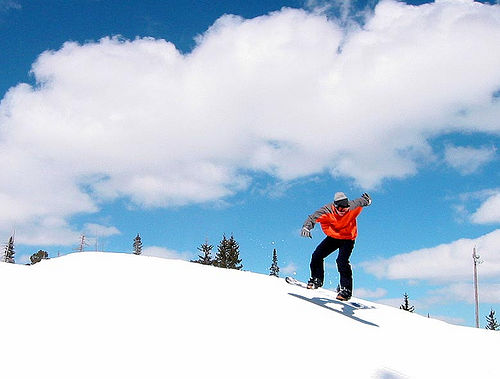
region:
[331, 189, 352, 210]
the head of a man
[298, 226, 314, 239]
the hand of a man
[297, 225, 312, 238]
a glove on the man's hand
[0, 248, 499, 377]
white snow on the ground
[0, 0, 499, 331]
a blue sky over the snow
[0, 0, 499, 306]
white clouds in the sky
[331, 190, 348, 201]
a gray hat on the man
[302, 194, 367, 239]
a gray and orange coat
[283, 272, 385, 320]
a white and gray snowboard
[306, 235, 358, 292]
a pair of black pants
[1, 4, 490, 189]
a big white clowd above the mountain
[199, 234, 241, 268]
green trees above the mountain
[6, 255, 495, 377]
a white snowy mountain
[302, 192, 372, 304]
a man on a snowboard jumping on the mountain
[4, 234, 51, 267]
more trees on the top of the mountain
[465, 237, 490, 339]
a pole on the side by the trees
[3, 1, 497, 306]
a bright blue sky with some clouds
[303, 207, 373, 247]
the mans red and grey jacket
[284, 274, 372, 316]
the man's snowboard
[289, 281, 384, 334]
the shadow of the man and his snowboard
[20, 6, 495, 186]
Cloudy sky on a sunny day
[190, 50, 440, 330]
Snowboarder on the slope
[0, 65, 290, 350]
Snow and clouds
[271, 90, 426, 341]
Snowboarder in red jacket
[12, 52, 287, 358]
Winter wonderland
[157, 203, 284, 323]
Conifers grown on the slope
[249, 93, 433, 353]
Outdoor adventures on a sunny day in winter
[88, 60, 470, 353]
A man enjoying snowboarding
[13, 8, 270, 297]
Blue sky and clouds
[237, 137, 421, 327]
Snowboarder in air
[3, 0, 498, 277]
a sky that is two different color blues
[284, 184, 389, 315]
a person on a snowboard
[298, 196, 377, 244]
an orange and grey jacket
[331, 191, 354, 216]
a motorcycle helmet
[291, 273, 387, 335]
shadow of the snowboarder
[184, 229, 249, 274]
top of trees over the hill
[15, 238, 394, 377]
a snow hill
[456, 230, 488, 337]
a wood utility pole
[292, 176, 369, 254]
snowboarder with one arm behind them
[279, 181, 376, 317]
Man snowboarding down hill.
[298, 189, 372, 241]
Man dressed in orange and gray jacket.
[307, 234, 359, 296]
Man dressed in black pants.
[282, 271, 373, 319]
Snowboard attached to man's feet.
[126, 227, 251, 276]
Tip of pine tree on mountain top.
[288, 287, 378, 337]
Shadow of man snowboarding.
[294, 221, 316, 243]
Man wearing gray glove on hand.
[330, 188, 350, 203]
Man wearing gray cap on head.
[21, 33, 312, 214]
White fluffy clouds in sky.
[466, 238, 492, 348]
Telephone pole mounted on top of hill.